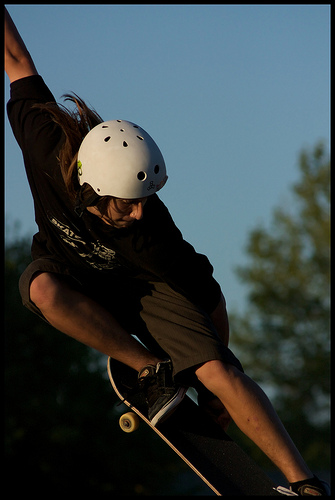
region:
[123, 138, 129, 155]
vent on top of helmet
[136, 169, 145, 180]
vent on top of helmet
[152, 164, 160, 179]
vent on top of helmet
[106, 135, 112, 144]
vent on top of helmet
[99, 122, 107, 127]
vent on top of helmet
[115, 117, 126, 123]
vent on top of helmet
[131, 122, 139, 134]
vent on top of helmet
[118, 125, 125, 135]
vent on top of helmet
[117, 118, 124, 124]
vent on top of helmet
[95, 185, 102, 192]
vent on top of helmet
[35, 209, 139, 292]
white lettering on black tee shirt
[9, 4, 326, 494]
skateboarder in the middle of a jump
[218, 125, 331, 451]
blurry green tree against a blue sky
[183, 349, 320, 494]
left leg of a skateboarder in a jump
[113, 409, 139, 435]
white plastic wheel on a skateboard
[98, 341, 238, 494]
black skateboard with light yellow trim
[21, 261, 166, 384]
right leg of a skateboarder in mid jump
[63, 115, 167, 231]
skateboarder's head with white helmet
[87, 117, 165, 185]
holes in the top of a white helmet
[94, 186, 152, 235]
face of a skateboarder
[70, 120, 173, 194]
a white skateboard helmet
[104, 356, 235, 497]
part of a black skateboard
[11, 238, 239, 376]
a man's black shorts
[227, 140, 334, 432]
part of a tall green tree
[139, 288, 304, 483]
the leg of a man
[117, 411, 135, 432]
a white skateboard wheel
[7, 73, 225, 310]
a man's black shirt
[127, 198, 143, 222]
the nose of a man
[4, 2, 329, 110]
part of a blue sky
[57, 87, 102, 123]
a piece of brown hair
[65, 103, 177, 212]
The skateboarder is wearing a helmet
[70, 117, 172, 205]
The helmet is white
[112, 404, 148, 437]
The skateboard wheels are tan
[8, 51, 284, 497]
The skateboarder is in the air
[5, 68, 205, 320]
Skateboarder is wearing a black shirt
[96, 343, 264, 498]
The skateboard is black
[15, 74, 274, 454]
The skateboarder has one hand on the board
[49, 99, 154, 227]
The person has long brown hair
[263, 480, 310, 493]
The shoe laces are white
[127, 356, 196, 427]
The shoes are black and white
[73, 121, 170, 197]
white helmet on woman's head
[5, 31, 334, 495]
woman riding a skateboard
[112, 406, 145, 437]
yellow wheel on the motorcycle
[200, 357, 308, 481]
leg of the woman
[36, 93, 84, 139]
brown hair on the woman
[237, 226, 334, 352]
green trees beside the woman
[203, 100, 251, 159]
clear blue sunny sky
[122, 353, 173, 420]
black and white sneaker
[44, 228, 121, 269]
white logo on the shirt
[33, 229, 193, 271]
woman wearing black shirt